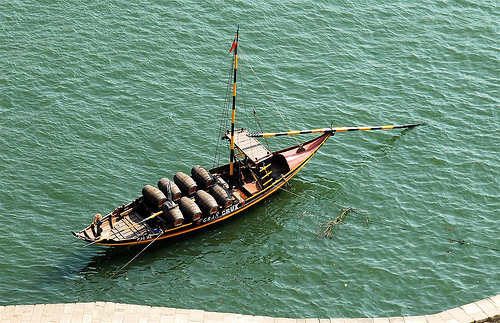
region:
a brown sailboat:
[70, 24, 420, 266]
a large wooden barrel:
[136, 182, 166, 204]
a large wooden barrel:
[154, 174, 178, 196]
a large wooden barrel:
[172, 170, 196, 192]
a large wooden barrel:
[187, 161, 210, 184]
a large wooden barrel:
[209, 182, 229, 205]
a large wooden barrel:
[190, 184, 217, 214]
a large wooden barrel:
[174, 192, 201, 221]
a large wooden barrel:
[160, 194, 183, 225]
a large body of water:
[0, 0, 494, 312]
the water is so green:
[315, 228, 403, 299]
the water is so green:
[330, 238, 398, 262]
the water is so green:
[345, 231, 432, 305]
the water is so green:
[336, 200, 403, 277]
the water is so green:
[326, 230, 381, 277]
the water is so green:
[350, 237, 384, 271]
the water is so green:
[367, 212, 435, 279]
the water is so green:
[353, 192, 395, 233]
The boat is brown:
[68, 126, 332, 244]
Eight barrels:
[142, 160, 228, 221]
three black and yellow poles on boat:
[80, 20, 415, 245]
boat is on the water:
[60, 25, 415, 245]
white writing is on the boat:
[195, 200, 240, 220]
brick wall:
[0, 295, 495, 320]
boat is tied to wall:
[75, 226, 175, 306]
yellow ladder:
[252, 150, 277, 191]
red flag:
[225, 40, 235, 55]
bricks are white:
[0, 293, 499, 322]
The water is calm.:
[368, 182, 440, 269]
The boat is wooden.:
[47, 117, 387, 262]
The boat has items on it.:
[70, 119, 342, 259]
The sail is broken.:
[240, 97, 455, 170]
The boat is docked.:
[86, 233, 191, 300]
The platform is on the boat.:
[220, 109, 282, 194]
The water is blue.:
[61, 23, 158, 136]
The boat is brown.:
[75, 114, 352, 244]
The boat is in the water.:
[50, 10, 353, 315]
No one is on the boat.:
[63, 94, 395, 295]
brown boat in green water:
[77, 131, 291, 244]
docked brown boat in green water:
[72, 147, 297, 256]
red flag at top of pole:
[225, 38, 240, 54]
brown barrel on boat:
[186, 161, 211, 181]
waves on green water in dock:
[14, 7, 185, 117]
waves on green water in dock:
[19, 98, 161, 167]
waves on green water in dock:
[215, 230, 452, 287]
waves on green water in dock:
[328, 156, 466, 254]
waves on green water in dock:
[253, 15, 375, 108]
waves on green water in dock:
[333, 7, 471, 111]